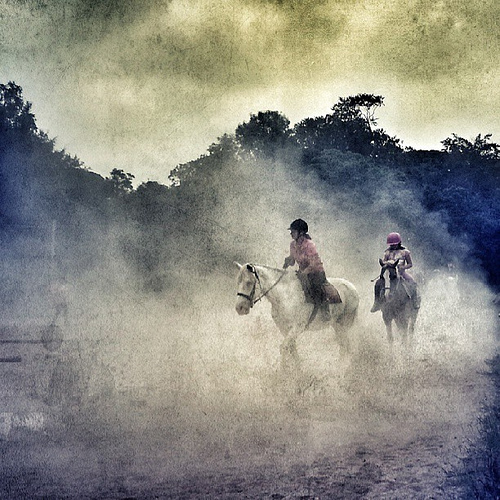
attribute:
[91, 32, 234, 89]
sky — mottled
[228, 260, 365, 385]
horse — white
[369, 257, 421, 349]
horse — dark, light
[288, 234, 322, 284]
shirt — pink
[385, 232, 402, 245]
helmet — pink